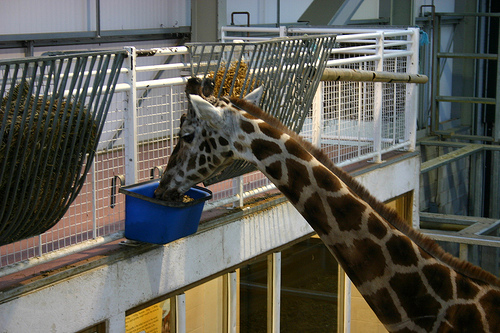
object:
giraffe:
[153, 73, 499, 333]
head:
[152, 72, 272, 212]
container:
[114, 175, 212, 246]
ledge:
[3, 141, 423, 332]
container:
[0, 48, 132, 248]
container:
[185, 37, 339, 185]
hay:
[2, 83, 102, 251]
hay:
[204, 56, 269, 119]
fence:
[2, 26, 429, 285]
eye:
[180, 129, 195, 144]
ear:
[186, 89, 224, 132]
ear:
[237, 81, 266, 110]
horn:
[185, 75, 202, 104]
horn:
[204, 77, 219, 97]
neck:
[248, 112, 499, 327]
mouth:
[152, 182, 183, 207]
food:
[180, 192, 197, 205]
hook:
[109, 171, 124, 212]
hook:
[150, 163, 162, 179]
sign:
[122, 304, 160, 332]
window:
[278, 232, 348, 332]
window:
[235, 248, 277, 332]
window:
[182, 264, 232, 331]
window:
[348, 189, 414, 332]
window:
[124, 293, 174, 332]